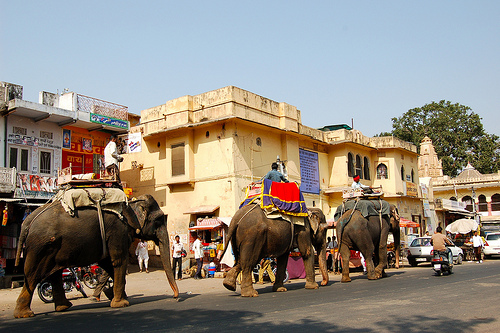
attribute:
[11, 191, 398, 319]
elephants — gray., walking.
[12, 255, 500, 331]
street. — gray.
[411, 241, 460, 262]
car — white.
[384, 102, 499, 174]
tree — green., large., bushy.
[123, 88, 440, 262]
building — tan., big.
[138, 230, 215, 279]
people — standing.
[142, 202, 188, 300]
trunk — long.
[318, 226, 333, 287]
trunk — long.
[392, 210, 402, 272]
trunk — long.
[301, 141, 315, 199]
sign — purple.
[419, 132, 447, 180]
tower — cylindrical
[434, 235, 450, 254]
shirt — peach.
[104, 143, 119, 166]
shirt — white.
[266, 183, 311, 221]
blanket — decorative., multicolored., purple., multicolored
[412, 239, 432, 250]
car — white.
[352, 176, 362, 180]
headband — red.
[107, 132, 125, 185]
man — standing.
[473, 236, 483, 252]
shirt — white.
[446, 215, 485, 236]
umbrella — tan.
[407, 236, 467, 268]
car — white., small.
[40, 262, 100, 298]
motorcycle — here.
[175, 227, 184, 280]
man — standing.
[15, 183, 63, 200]
sign — hanging.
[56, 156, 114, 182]
fence — gray.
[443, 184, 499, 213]
windows — arched.